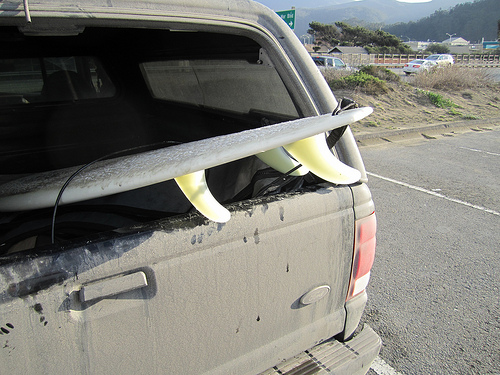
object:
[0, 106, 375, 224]
surfboard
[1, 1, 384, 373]
suv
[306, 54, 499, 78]
street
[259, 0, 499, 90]
background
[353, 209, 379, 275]
brake lights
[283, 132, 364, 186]
fin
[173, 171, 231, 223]
fin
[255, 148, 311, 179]
fin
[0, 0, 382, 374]
dust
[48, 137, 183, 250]
cord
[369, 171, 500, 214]
lines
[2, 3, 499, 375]
parking lot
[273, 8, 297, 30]
street sign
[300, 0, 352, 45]
hills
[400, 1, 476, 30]
mountains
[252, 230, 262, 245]
spots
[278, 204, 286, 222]
spots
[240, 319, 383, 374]
back bumper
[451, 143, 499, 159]
stripe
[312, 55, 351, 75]
car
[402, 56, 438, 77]
car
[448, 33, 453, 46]
light pole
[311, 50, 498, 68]
fence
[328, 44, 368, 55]
house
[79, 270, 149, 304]
handle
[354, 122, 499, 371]
road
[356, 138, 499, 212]
parking space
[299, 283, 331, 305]
brand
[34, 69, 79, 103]
front seat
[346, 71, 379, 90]
grass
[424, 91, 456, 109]
grass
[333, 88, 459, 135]
dirt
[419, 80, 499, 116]
dirt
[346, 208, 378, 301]
tail light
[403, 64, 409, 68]
tail lights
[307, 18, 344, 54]
evergreen shrub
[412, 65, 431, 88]
grass shrub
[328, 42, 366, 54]
roof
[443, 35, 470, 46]
house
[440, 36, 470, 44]
roof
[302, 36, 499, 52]
residential area